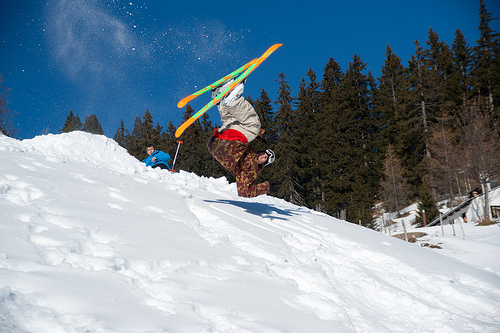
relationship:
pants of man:
[213, 77, 260, 141] [207, 74, 277, 198]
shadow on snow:
[237, 191, 287, 222] [7, 136, 483, 307]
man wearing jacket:
[140, 142, 173, 179] [141, 150, 173, 168]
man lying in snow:
[140, 142, 173, 179] [3, 130, 495, 332]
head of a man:
[253, 148, 274, 166] [150, 22, 351, 226]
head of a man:
[253, 148, 274, 166] [213, 78, 283, 201]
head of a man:
[253, 148, 274, 166] [203, 62, 278, 202]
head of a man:
[253, 148, 274, 166] [162, 30, 309, 211]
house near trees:
[388, 167, 468, 234] [300, 50, 495, 198]